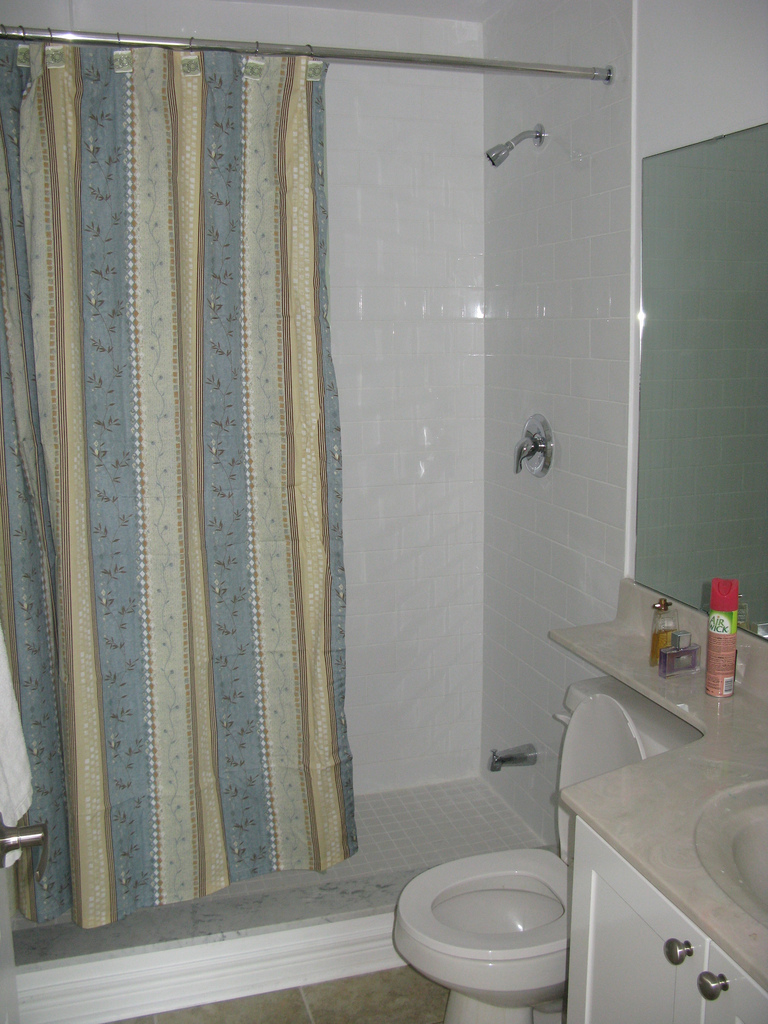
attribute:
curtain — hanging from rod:
[4, 13, 396, 905]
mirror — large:
[633, 118, 767, 570]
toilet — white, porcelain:
[345, 678, 692, 1015]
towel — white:
[0, 622, 71, 832]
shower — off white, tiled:
[144, 244, 564, 675]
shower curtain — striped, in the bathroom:
[0, 25, 364, 913]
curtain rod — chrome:
[3, 13, 618, 89]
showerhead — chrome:
[478, 113, 549, 175]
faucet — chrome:
[476, 725, 540, 786]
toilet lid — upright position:
[545, 683, 653, 892]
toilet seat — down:
[387, 841, 586, 968]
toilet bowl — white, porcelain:
[397, 831, 578, 1020]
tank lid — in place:
[556, 676, 706, 784]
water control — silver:
[508, 412, 558, 484]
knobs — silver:
[651, 919, 744, 1008]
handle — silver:
[0, 810, 55, 868]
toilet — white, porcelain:
[383, 682, 639, 1021]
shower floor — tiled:
[198, 771, 566, 914]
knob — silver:
[658, 921, 733, 1007]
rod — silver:
[2, 23, 626, 81]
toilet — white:
[393, 690, 654, 1020]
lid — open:
[553, 675, 659, 895]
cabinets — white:
[567, 798, 720, 999]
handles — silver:
[571, 863, 742, 1022]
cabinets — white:
[538, 794, 730, 1020]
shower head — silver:
[452, 100, 535, 189]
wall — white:
[437, 114, 650, 573]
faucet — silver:
[487, 395, 558, 552]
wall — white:
[452, 118, 629, 648]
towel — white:
[1, 603, 65, 857]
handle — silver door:
[0, 811, 57, 862]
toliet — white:
[383, 647, 697, 991]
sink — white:
[504, 694, 755, 874]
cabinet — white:
[513, 812, 729, 1013]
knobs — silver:
[612, 917, 737, 1007]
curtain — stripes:
[95, 47, 406, 887]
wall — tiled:
[381, 164, 604, 585]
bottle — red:
[668, 575, 733, 745]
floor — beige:
[219, 950, 466, 998]